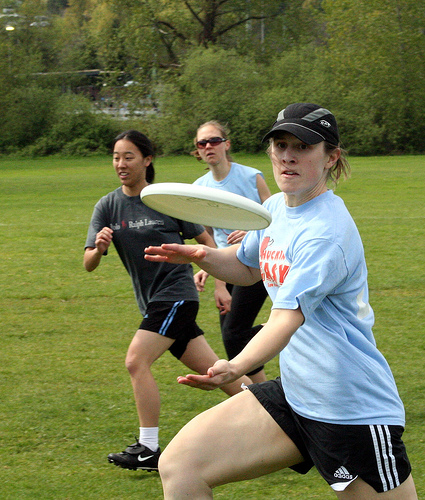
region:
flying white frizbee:
[138, 181, 270, 230]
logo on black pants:
[332, 463, 353, 479]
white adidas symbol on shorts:
[333, 465, 354, 480]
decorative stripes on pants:
[370, 424, 401, 490]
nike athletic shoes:
[105, 442, 165, 472]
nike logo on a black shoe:
[137, 454, 153, 461]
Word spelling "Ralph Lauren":
[126, 217, 166, 227]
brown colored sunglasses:
[194, 135, 225, 148]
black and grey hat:
[260, 102, 342, 146]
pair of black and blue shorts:
[136, 298, 203, 359]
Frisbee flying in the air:
[141, 182, 272, 231]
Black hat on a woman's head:
[258, 102, 339, 146]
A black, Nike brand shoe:
[108, 442, 163, 472]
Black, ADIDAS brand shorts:
[247, 377, 413, 493]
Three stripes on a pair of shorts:
[366, 421, 398, 489]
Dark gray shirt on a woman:
[83, 184, 205, 306]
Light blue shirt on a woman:
[236, 190, 409, 427]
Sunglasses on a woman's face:
[194, 136, 229, 147]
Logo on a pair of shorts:
[333, 464, 354, 479]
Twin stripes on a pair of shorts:
[158, 299, 186, 334]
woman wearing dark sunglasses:
[194, 136, 227, 147]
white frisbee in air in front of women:
[140, 181, 271, 230]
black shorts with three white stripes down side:
[245, 371, 409, 491]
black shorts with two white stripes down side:
[137, 302, 205, 360]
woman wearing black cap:
[262, 102, 338, 151]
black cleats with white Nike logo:
[108, 442, 160, 472]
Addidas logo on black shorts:
[331, 464, 355, 480]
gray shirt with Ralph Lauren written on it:
[83, 185, 208, 313]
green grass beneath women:
[1, 155, 422, 498]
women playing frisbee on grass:
[78, 102, 418, 498]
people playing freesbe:
[78, 55, 422, 359]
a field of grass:
[15, 317, 127, 491]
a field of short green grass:
[40, 341, 183, 480]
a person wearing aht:
[217, 103, 357, 243]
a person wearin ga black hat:
[247, 118, 400, 248]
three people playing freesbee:
[68, 128, 406, 370]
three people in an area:
[70, 126, 421, 459]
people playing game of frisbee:
[75, 99, 393, 498]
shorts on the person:
[238, 368, 410, 486]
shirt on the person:
[237, 193, 406, 421]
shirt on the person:
[86, 187, 206, 292]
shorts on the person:
[137, 290, 199, 341]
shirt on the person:
[189, 165, 262, 256]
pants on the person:
[208, 272, 269, 371]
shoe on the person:
[110, 439, 160, 472]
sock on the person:
[133, 421, 160, 446]